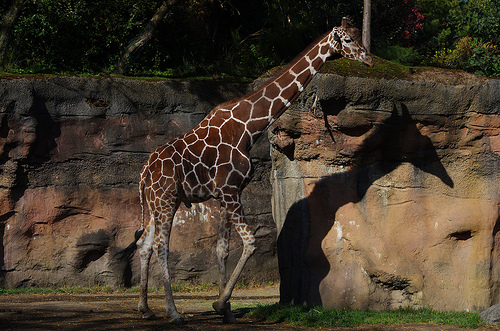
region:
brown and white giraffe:
[113, 18, 373, 313]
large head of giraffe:
[321, 13, 367, 68]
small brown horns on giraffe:
[336, 12, 352, 23]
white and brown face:
[335, 30, 375, 61]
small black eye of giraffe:
[336, 37, 351, 40]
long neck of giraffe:
[213, 35, 333, 126]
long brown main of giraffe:
[246, 38, 324, 95]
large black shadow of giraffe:
[275, 105, 443, 296]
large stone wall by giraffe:
[311, 100, 472, 276]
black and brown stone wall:
[1, 83, 114, 283]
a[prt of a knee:
[376, 179, 416, 232]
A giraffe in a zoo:
[130, 6, 382, 317]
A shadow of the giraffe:
[281, 97, 455, 284]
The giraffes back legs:
[136, 249, 178, 329]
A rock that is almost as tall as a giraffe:
[313, 61, 479, 299]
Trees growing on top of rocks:
[89, 4, 179, 74]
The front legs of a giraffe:
[213, 174, 261, 324]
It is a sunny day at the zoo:
[216, 69, 458, 278]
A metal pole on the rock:
[353, 0, 392, 70]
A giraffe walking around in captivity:
[104, 124, 319, 303]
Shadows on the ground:
[21, 274, 239, 327]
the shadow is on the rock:
[319, 100, 486, 201]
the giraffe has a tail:
[129, 189, 151, 243]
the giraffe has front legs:
[210, 202, 253, 315]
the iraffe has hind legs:
[122, 198, 193, 329]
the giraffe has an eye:
[343, 34, 356, 51]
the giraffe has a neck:
[259, 52, 321, 107]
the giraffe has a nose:
[361, 47, 376, 76]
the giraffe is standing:
[66, 14, 392, 311]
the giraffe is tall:
[108, 11, 390, 328]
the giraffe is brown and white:
[119, 16, 381, 326]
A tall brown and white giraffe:
[133, 29, 387, 329]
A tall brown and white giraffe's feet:
[147, 201, 180, 321]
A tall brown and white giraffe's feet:
[225, 195, 268, 330]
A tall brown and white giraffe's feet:
[132, 234, 158, 324]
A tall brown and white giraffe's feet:
[213, 208, 235, 326]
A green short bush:
[422, 29, 489, 61]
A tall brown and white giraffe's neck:
[257, 24, 359, 144]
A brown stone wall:
[337, 144, 497, 298]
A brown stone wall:
[283, 111, 339, 304]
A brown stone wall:
[20, 114, 138, 296]